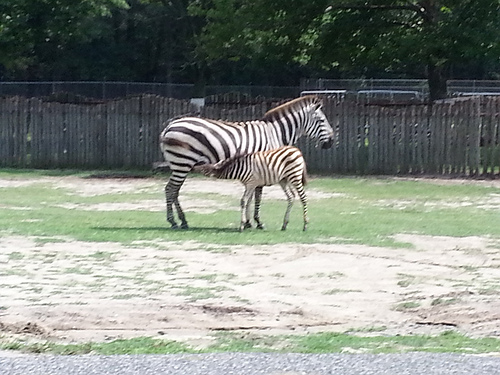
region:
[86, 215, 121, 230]
this is the grass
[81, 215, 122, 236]
the grass is green in color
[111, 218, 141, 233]
the grass is short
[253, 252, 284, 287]
this is the ground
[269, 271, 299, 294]
the ground is sandy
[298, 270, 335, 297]
the sand is brown in color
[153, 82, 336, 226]
these are some zebras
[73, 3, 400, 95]
these are some trees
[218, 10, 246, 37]
the leaves are green in color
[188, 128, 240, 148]
the fur is black and white in color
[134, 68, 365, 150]
black and white zebra in grass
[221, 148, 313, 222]
black and white zebra in grass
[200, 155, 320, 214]
zebra trying to get milk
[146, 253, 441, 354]
dirt patches in grass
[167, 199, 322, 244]
grass patches around dirt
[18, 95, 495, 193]
wood fence around zebras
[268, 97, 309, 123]
stiff mane on zebra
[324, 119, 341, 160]
black nose of zebra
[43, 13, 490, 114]
green trees in background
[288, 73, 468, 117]
white vehicles behind fence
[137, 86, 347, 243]
two zebras standing in the grass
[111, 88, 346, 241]
looks to be a mom and a baby zebra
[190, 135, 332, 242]
the baby zebra is under mom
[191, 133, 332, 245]
the baby zebra is shorter than mom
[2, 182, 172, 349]
there is dry dirt and grass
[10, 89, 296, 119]
the fence is not flat on top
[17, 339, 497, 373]
you can see pavement by the grass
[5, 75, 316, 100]
you can see a chain link fence beyond the wooden fence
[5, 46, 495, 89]
you can see partial trees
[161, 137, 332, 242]
the baby is looking to eat